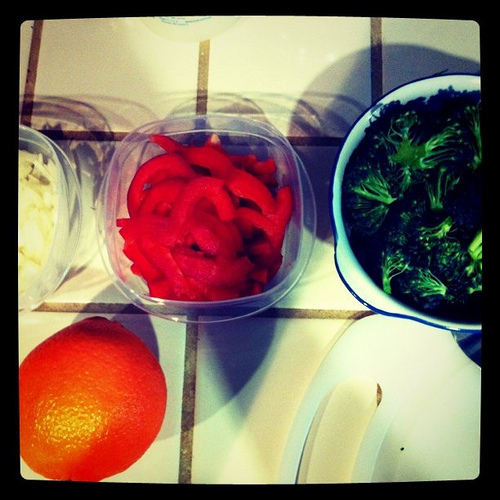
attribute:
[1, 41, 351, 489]
lines — grey, grout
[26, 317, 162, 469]
fruit — orange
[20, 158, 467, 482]
counter — grey, white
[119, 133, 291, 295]
peppers — red, sliced, bell peppers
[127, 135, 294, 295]
bowl — clear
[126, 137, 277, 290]
food — healthy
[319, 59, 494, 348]
bowl — white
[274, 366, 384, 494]
banana — fresh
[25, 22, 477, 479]
countertop — tile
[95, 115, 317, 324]
bowl — plastic